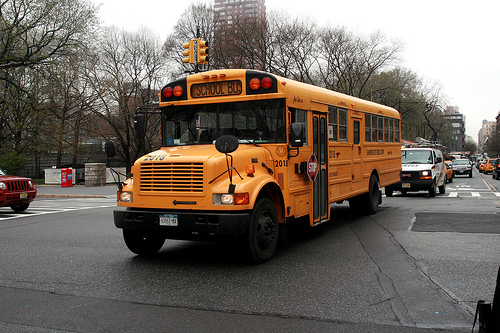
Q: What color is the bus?
A: Yellow.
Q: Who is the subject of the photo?
A: The bus.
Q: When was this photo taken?
A: During the day.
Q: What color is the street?
A: Gray.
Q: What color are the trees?
A: Brown.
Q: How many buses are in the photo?
A: One.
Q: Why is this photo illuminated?
A: Sunlight.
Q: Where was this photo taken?
A: On the street.